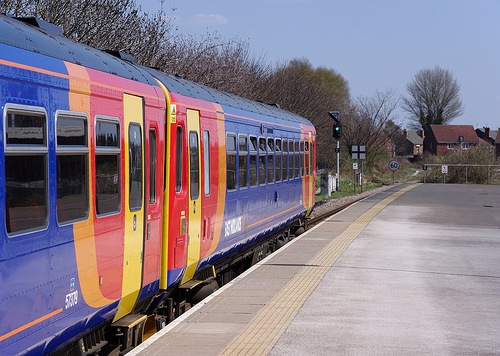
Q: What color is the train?
A: Red, blue yellow, and orange.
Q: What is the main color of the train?
A: Blue.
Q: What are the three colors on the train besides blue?
A: Red, yellow, and orange.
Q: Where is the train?
A: On the tracks.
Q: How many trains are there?
A: One.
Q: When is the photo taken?
A: During the day.